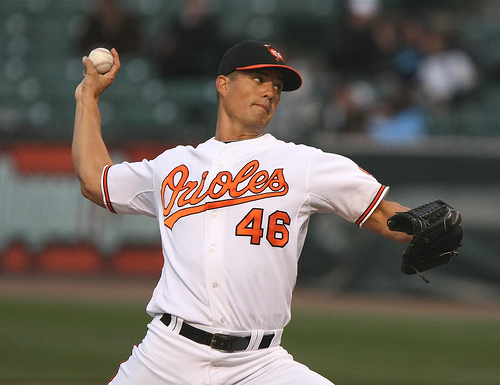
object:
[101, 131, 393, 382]
pitcher's unifrom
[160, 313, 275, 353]
belt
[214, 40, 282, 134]
head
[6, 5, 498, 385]
baseball game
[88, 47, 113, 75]
ball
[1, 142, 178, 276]
advertisement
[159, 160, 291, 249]
name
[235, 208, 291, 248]
46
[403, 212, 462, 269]
hand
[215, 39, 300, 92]
hat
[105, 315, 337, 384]
pants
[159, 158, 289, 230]
logo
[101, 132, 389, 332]
jersey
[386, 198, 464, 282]
baseball glove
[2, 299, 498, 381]
grass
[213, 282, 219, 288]
button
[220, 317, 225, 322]
button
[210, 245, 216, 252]
button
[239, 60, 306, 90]
brim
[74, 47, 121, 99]
hand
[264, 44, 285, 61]
oriole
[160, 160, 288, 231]
orioles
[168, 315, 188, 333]
belt loops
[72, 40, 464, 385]
baseball player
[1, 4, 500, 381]
photo